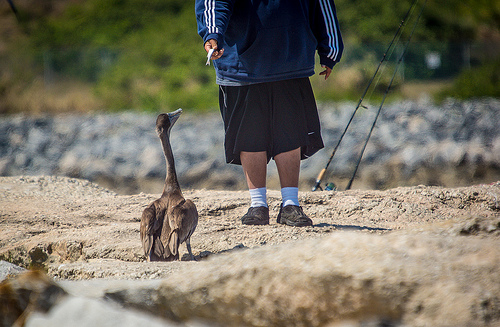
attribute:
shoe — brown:
[242, 206, 269, 227]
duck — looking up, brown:
[140, 109, 198, 263]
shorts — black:
[216, 81, 326, 166]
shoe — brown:
[278, 205, 314, 226]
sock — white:
[281, 187, 298, 208]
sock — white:
[250, 187, 270, 206]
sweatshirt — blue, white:
[196, 1, 343, 83]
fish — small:
[207, 49, 213, 68]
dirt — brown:
[428, 200, 441, 211]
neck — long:
[162, 142, 181, 193]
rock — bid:
[454, 220, 475, 234]